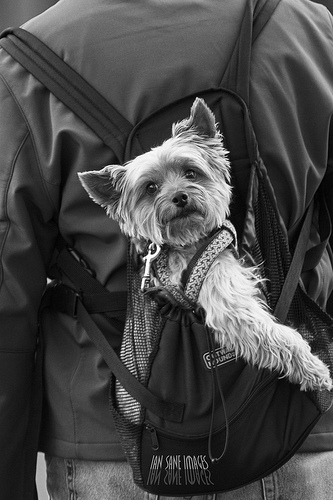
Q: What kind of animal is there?
A: A dog.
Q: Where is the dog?
A: In the bag.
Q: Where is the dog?
A: In a bag.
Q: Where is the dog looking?
A: At camera.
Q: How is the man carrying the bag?
A: On back.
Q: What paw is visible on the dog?
A: Right paw.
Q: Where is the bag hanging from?
A: Shoulders.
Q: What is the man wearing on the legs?
A: Jeans.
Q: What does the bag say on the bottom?
A: Ian sane images.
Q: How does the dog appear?
A: Comfortable.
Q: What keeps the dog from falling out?
A: Harness.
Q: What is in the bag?
A: A dog.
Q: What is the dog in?
A: A backpack.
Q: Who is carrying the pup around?
A: The owner.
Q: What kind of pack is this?
A: A doggy pack.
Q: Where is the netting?
A: On the doggy pack.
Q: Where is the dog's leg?
A: Outside the pack.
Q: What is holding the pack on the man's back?
A: Straps.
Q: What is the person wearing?
A: A jacket.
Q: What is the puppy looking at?
A: The camera.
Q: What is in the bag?
A: A dog.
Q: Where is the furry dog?
A: In the bag.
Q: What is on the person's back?
A: A dog.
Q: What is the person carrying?
A: A dog.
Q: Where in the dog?
A: In the black bag.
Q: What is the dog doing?
A: Posing for the camera.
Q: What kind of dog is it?
A: Terrier.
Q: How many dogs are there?
A: One.